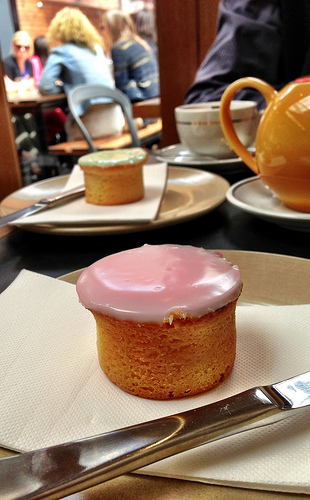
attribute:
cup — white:
[174, 99, 264, 159]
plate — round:
[65, 228, 305, 388]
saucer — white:
[224, 172, 309, 230]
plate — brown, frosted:
[2, 152, 228, 235]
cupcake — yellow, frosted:
[74, 147, 149, 205]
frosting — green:
[76, 147, 145, 170]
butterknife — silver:
[9, 186, 90, 222]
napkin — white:
[0, 266, 309, 495]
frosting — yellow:
[75, 144, 149, 171]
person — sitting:
[161, 12, 301, 81]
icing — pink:
[63, 235, 253, 320]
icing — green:
[66, 137, 154, 168]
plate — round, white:
[9, 125, 244, 241]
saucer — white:
[130, 113, 280, 184]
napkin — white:
[13, 275, 308, 487]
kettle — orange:
[216, 66, 309, 224]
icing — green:
[78, 149, 142, 158]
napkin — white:
[6, 188, 167, 224]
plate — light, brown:
[0, 156, 233, 242]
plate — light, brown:
[0, 244, 309, 497]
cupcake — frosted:
[74, 239, 244, 403]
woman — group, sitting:
[5, 24, 38, 109]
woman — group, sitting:
[39, 4, 119, 143]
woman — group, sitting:
[95, 5, 159, 104]